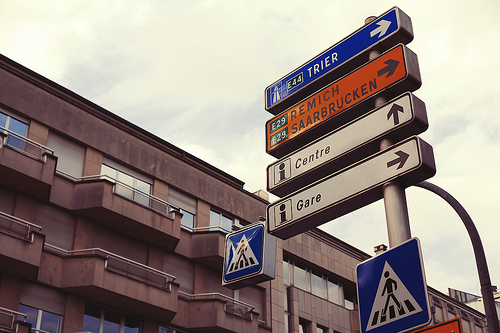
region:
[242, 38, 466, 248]
Street signs are stacked on top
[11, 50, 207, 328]
A building is in the background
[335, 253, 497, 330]
A pedestrian sign is blue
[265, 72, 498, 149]
The sign was orange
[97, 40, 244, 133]
The sky is cloudy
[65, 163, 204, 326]
Balconies are on the building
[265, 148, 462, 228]
The signs are white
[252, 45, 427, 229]
The signs are on a pole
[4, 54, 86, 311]
The building is brown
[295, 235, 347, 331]
Brown tile is above the window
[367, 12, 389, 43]
arrow on the blue sign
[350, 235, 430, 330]
sign with triangle on the pole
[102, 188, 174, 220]
balcony on the building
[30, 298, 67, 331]
windows on the building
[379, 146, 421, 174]
arrow on the white sign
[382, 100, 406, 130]
white sign with arrow facing up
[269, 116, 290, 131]
E29 on the orange sign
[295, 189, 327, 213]
Gare on the sign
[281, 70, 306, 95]
E44 on the sign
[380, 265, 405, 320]
person on the triangle sign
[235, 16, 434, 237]
street signs on a pole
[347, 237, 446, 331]
blue square street sign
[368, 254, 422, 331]
white triangle on street sign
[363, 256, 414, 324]
person walking on street sign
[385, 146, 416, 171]
block arrow on street sign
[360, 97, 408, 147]
black arrow on street sign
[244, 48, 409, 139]
orange street sign on pole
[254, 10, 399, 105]
blue street sign on pole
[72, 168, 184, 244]
balcony on side of building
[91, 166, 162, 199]
windows on side of building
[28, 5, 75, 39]
white clouds in blue sky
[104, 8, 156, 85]
white clouds in blue sky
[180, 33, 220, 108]
white clouds in blue sky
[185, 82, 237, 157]
white clouds in blue sky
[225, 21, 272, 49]
white clouds in blue sky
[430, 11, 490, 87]
white clouds in blue sky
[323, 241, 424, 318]
blue and white sign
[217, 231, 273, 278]
blue and white sign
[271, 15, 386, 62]
blue and white sign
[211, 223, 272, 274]
black blue and white sign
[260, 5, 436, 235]
long horizontal signs lined up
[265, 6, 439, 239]
four signs lined up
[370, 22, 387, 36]
white arrow at the top of sign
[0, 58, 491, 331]
large brown apartment complex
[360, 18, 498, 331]
metal pole with signs on it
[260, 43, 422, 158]
red sign in the middle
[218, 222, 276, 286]
blue sign on the left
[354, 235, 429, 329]
blue sign at the end of the pole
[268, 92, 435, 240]
white signs with black arrows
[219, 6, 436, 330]
six street signs